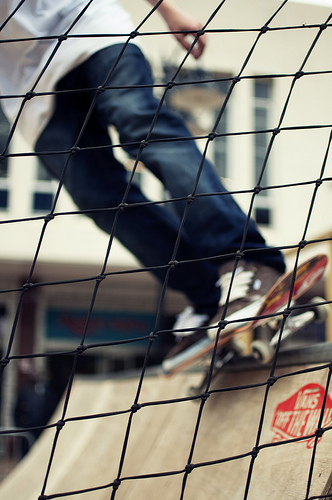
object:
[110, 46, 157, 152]
thigh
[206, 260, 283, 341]
sneaker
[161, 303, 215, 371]
sneaker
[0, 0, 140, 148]
shirt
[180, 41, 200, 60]
finger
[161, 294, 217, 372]
feet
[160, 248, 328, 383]
skateboard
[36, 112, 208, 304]
legs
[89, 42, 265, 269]
leg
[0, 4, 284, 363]
person